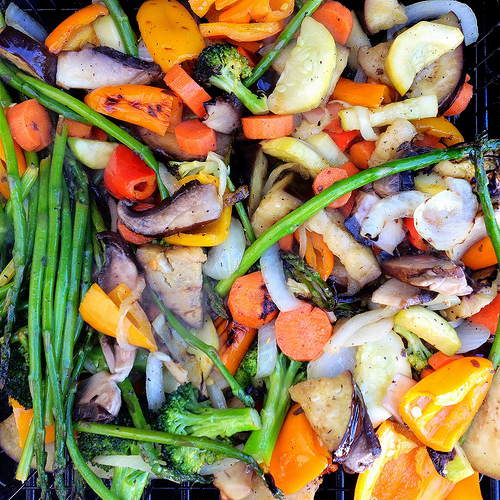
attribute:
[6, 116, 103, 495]
vegetables — long, green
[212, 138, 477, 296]
asparagus — single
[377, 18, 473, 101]
squash — yellow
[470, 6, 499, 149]
rack — metal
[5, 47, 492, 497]
vegetables — assorted, grilled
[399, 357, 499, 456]
pepper — yellow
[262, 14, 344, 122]
squash — yellow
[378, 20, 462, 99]
squash — yellow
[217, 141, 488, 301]
food — green, piece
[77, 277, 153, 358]
food — piece, yellow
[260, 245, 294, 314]
food — piece, white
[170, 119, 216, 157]
food — orange, piece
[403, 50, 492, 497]
side — right hand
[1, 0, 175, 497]
side — left hand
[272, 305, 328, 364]
carrot — round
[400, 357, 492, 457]
peppers — yellow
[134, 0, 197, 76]
peppers — yellow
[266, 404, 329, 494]
peppers — yellow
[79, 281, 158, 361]
peppers — yellow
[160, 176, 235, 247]
peppers — yellow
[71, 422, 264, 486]
bean — green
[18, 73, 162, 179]
bean — green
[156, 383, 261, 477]
broccoli — green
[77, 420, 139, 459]
broccoli — green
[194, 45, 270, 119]
broccoli — green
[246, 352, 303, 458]
broccoli — green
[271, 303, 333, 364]
carrot — orange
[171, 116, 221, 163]
carrot — orange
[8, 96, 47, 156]
carrot — orange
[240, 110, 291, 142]
carrot — orange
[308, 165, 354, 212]
carrot — orange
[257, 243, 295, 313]
onion — white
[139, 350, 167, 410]
onion — white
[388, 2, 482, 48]
onion — white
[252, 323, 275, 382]
onion — white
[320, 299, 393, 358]
onion — white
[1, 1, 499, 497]
rack — metallic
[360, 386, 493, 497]
bellpeppers — yellow